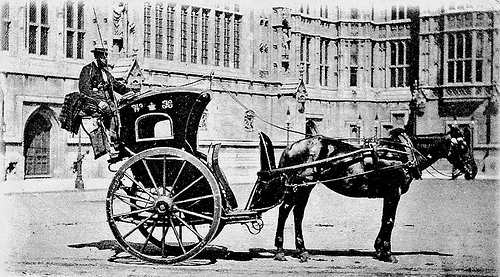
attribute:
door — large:
[23, 101, 58, 178]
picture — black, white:
[6, 4, 498, 274]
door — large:
[20, 105, 53, 174]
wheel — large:
[104, 144, 224, 262]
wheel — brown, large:
[107, 141, 228, 266]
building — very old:
[4, 2, 498, 200]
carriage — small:
[104, 86, 271, 264]